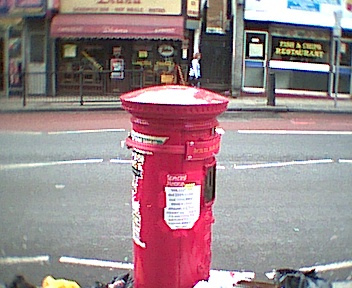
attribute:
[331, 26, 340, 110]
pole — gray, metal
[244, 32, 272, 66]
restaurant — Small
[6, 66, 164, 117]
fencing — black, metal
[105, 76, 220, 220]
post — red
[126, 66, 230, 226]
metal — Red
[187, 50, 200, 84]
woman — one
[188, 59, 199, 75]
jacket — light colored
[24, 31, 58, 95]
door — one, white, rectangular, storm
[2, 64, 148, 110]
fence — Black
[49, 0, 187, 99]
building — commercial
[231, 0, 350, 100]
building — commercial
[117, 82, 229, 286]
hydrant — red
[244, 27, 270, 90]
door — restaurant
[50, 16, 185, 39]
awning — dark red, canvas, shop